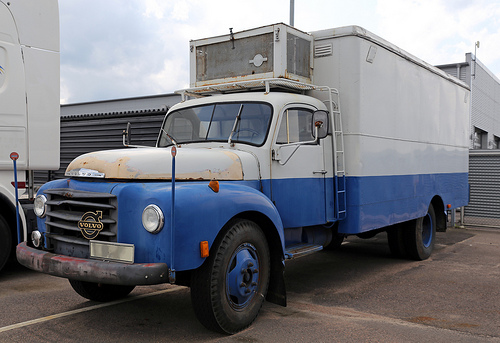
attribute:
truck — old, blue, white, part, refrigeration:
[20, 18, 482, 337]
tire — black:
[189, 212, 282, 340]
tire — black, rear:
[387, 197, 441, 265]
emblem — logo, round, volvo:
[76, 209, 107, 244]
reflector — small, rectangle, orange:
[198, 235, 212, 260]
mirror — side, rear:
[308, 102, 331, 138]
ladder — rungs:
[315, 80, 351, 220]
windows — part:
[154, 98, 276, 155]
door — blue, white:
[264, 95, 332, 233]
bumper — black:
[13, 236, 174, 296]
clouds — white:
[139, 2, 500, 92]